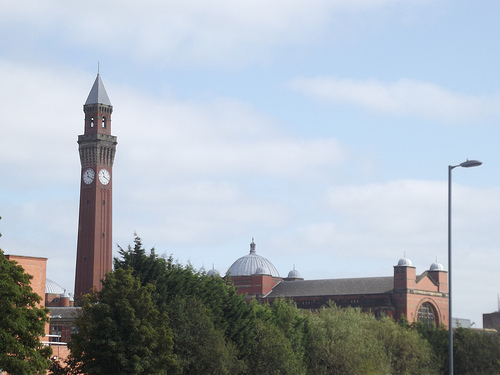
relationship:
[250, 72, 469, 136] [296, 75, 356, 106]
cloud has a part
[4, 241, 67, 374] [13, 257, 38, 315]
tree has a part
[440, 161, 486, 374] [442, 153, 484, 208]
post has a part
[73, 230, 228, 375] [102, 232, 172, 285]
bush has a top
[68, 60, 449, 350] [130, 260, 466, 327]
church has an edge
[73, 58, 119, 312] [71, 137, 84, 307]
tower has an edge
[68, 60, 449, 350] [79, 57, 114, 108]
church has a tip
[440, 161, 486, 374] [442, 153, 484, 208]
lamp has a part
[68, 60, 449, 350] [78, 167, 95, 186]
church has a clock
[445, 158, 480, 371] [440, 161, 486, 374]
street has a light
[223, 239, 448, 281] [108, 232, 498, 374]
domes on building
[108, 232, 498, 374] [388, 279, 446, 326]
buildings are made of brick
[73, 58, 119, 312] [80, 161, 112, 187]
tower has two clocks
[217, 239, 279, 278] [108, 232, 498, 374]
dome on a building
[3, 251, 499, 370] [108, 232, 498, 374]
trees by building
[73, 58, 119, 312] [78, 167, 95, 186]
tower has a clock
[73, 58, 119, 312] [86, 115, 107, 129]
tower has windows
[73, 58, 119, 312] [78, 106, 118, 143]
tower with a gazebo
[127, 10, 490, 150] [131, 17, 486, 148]
clouds in sky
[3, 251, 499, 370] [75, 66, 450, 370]
trees outside church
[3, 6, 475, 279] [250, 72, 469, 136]
part of cloud